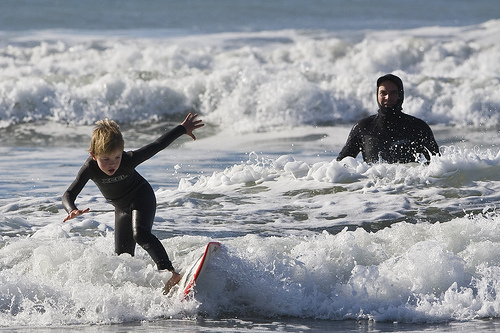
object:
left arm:
[132, 126, 185, 168]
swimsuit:
[62, 125, 187, 270]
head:
[376, 73, 403, 108]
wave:
[14, 39, 496, 114]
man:
[337, 73, 440, 163]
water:
[0, 0, 498, 331]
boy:
[62, 113, 204, 287]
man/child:
[60, 74, 441, 285]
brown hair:
[91, 123, 123, 155]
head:
[90, 122, 124, 175]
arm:
[62, 166, 90, 213]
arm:
[418, 119, 439, 160]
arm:
[336, 123, 358, 158]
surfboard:
[179, 242, 221, 301]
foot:
[164, 273, 181, 295]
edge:
[182, 244, 210, 296]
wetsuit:
[337, 109, 440, 162]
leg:
[133, 204, 175, 271]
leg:
[114, 208, 136, 256]